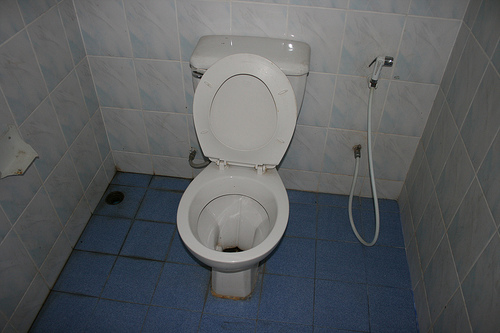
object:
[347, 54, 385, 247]
hose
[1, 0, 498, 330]
bathroom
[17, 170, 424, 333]
ground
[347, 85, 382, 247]
white cord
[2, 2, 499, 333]
stall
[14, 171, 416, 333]
floor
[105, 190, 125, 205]
brown spot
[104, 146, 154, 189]
corner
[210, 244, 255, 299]
spot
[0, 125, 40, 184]
dispenser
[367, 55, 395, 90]
spray gun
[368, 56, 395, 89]
faucet handle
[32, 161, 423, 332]
tile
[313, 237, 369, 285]
blue tile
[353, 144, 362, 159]
spot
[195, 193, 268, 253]
bowl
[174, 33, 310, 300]
toilet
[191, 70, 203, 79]
flush handle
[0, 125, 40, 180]
roll holder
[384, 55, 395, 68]
spout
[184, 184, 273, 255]
interior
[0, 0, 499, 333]
wall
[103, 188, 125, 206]
spot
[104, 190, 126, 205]
drain